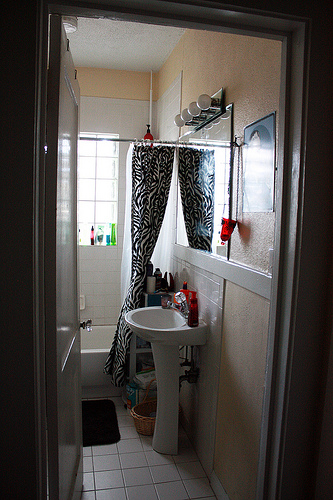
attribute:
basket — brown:
[126, 376, 184, 438]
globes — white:
[171, 91, 221, 127]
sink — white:
[123, 303, 207, 455]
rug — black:
[81, 390, 129, 451]